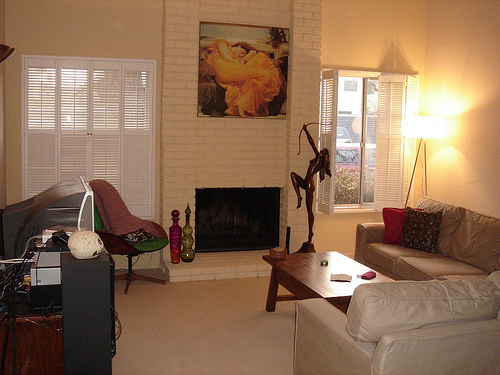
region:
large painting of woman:
[196, 17, 293, 123]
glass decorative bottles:
[165, 199, 201, 265]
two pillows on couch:
[382, 202, 444, 254]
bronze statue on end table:
[289, 120, 341, 259]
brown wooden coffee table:
[259, 251, 400, 316]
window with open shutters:
[320, 57, 421, 221]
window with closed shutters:
[21, 51, 166, 235]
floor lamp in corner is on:
[405, 110, 449, 224]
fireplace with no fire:
[192, 181, 292, 263]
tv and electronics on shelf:
[3, 163, 118, 318]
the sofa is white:
[349, 277, 449, 365]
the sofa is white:
[375, 292, 436, 350]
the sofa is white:
[353, 298, 410, 369]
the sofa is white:
[360, 317, 418, 344]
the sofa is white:
[333, 302, 390, 367]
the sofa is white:
[347, 242, 422, 340]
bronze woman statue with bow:
[277, 107, 332, 255]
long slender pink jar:
[167, 205, 183, 268]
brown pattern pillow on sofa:
[401, 207, 441, 254]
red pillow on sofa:
[382, 198, 411, 243]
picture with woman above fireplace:
[190, 11, 296, 125]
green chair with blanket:
[90, 173, 175, 287]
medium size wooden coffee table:
[268, 242, 381, 303]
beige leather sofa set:
[277, 190, 497, 369]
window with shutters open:
[319, 59, 419, 209]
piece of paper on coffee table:
[327, 265, 353, 287]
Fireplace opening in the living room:
[187, 171, 287, 254]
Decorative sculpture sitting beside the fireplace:
[282, 111, 334, 265]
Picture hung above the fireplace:
[190, 16, 288, 118]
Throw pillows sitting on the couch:
[370, 198, 459, 263]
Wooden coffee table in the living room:
[249, 243, 399, 313]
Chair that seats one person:
[84, 174, 169, 289]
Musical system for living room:
[13, 236, 112, 298]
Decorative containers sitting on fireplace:
[167, 200, 197, 268]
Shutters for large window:
[27, 56, 162, 234]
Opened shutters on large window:
[318, 67, 410, 219]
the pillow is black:
[405, 202, 499, 297]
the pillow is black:
[396, 207, 463, 255]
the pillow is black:
[365, 207, 473, 294]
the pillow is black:
[420, 205, 447, 255]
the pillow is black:
[386, 178, 488, 275]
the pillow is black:
[390, 201, 447, 281]